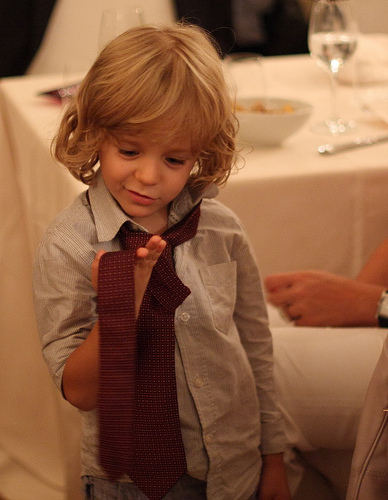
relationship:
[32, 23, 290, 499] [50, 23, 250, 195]
boy has hair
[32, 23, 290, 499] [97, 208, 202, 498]
boy wearing tie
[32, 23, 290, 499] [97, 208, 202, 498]
boy looking tie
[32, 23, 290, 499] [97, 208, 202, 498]
boy has tie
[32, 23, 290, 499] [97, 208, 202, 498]
boy holding tie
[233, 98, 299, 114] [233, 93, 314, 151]
food in bowl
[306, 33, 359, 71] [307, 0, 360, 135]
water in glass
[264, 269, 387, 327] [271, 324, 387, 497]
hand over lap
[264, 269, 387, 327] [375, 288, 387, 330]
hand has watch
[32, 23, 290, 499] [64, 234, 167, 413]
boy has hand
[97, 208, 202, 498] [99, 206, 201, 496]
tie has dots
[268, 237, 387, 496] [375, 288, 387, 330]
person wearing watch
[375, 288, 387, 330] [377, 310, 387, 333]
watch has band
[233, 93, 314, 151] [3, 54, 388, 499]
bowl on top of table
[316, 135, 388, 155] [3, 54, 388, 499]
knife on top of table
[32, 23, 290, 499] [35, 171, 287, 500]
boy wearing shirt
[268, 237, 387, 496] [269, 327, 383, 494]
person wearing pants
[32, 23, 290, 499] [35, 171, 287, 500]
boy has shirt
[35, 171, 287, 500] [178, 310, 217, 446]
shirt has buttons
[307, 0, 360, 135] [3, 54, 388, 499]
glass on top of table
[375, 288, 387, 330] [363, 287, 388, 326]
watch on wrist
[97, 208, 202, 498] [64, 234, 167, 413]
tie in hand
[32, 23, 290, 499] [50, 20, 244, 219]
boy has head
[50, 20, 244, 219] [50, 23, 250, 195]
head has hair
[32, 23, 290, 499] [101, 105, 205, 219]
boy has face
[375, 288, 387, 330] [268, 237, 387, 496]
watch on person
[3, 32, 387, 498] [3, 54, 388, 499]
table cloth on table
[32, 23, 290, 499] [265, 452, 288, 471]
boy has wrist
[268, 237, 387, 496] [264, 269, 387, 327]
person has hand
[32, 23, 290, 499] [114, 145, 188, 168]
boy has eyes